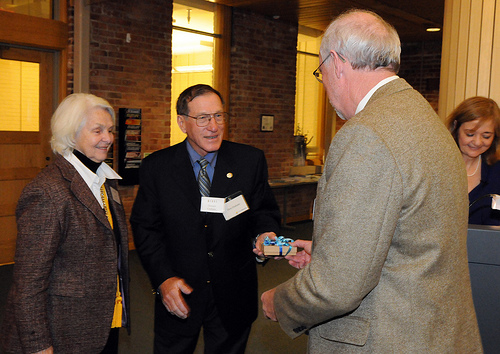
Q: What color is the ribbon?
A: Blue.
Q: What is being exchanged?
A: A gift.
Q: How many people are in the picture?
A: Four.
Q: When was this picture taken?
A: During a convention.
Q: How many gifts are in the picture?
A: One.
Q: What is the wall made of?
A: Brick.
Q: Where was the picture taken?
A: Inside a building.